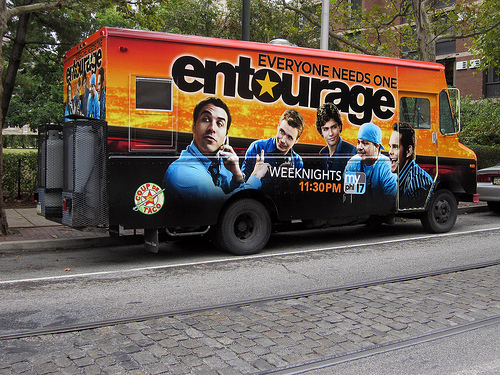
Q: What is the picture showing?
A: A bus advertisement.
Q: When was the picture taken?
A: During the day.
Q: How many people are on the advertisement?
A: Five.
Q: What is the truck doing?
A: Parked.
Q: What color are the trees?
A: Green.